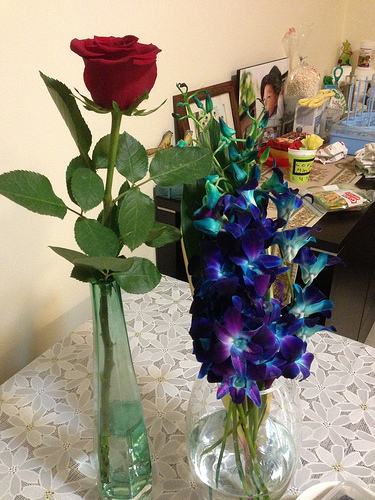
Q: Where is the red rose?
A: In the vase on the left.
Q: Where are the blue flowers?
A: In a vase on the right.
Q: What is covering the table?
A: A white flowered tablecloth.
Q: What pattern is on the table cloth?
A: Flowers.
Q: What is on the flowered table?
A: Flowers.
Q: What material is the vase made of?
A: Glass.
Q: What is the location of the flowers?
A: In the vase.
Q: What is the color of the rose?
A: Red.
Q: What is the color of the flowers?
A: Purple.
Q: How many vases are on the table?
A: Two.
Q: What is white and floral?
A: Tablecloth.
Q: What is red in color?
A: Rose.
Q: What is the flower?
A: Rose.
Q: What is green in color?
A: Stem.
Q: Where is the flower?
A: On a table.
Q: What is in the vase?
A: Flower.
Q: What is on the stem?
A: Flower.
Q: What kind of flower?
A: Rose.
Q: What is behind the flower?
A: Pictures.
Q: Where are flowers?
A: In a vase.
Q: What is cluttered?
A: A table.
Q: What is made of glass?
A: The vases.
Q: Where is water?
A: In vases.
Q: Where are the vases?
A: On a table.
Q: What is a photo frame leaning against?
A: The wall.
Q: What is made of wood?
A: Photo frame.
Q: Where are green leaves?
A: On red rose.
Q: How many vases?
A: Two.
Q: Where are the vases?
A: On the table.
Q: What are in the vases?
A: Flowers.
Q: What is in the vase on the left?
A: A rose.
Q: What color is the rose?
A: Red.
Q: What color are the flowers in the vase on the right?
A: Blue.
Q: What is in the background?
A: A desk.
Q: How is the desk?
A: Messy.